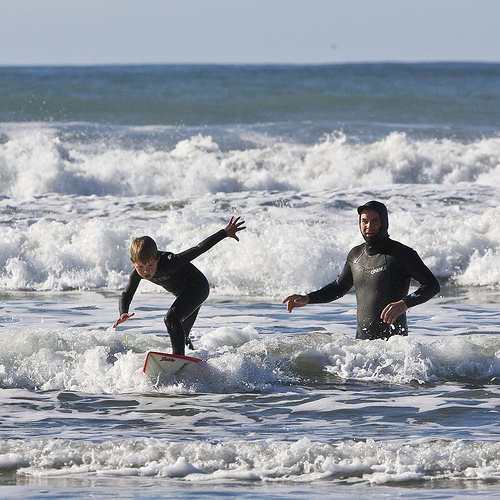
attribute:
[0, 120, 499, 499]
waves — rolling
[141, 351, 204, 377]
surfboard — Red 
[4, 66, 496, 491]
water — white , blue 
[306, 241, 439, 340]
wetsuit — black 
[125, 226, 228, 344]
wetsuit — black 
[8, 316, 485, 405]
wave — Small 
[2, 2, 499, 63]
sky — blue , overcast 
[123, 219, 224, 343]
wetsuit — Black 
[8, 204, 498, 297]
wave — White 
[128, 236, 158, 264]
hair — Brown 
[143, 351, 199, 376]
surfboard — Red , white 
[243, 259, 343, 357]
water — blue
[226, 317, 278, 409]
water — wavy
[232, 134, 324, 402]
water — blue, wavy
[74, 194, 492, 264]
water — blue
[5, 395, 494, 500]
wave — white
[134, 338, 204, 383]
surfboard — white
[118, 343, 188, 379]
surfboard edge — red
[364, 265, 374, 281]
letter — white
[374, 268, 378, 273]
letter — white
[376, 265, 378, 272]
letter — white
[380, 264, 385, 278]
letter — white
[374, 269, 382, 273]
letter — white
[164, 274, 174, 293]
letter — white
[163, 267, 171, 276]
letter — white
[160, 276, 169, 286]
letter — WHITE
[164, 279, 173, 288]
letter — WHITE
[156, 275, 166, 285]
letter — WHITE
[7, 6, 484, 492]
scene — outdoors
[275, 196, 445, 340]
wet suit — black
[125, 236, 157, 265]
hair — blond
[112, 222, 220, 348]
wet suit — black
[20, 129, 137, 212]
wave — white, foamy, crashing